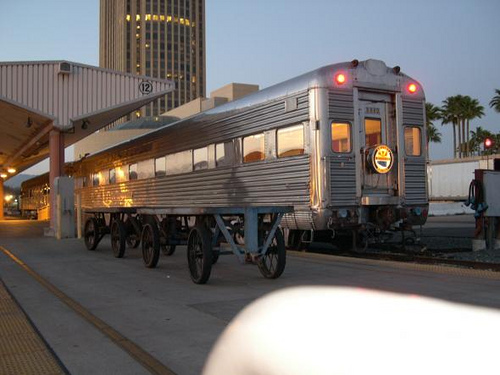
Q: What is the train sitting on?
A: Rails.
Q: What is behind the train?
A: Building.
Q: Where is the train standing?
A: At the station.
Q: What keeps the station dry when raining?
A: Roof covering.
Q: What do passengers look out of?
A: Windows.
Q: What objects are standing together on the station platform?
A: Wheels.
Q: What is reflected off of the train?
A: Sunset.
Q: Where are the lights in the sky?
A: In the building.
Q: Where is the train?
A: On the tracks.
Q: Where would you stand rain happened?
A: Under the overhang.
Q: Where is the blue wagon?
A: On the train platform.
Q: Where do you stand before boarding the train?
A: On the train platform.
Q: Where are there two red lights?
A: On the front of the train.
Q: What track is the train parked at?
A: Track 12.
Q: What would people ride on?
A: The train.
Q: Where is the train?
A: Parked at the platform.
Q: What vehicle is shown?
A: Train.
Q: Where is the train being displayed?
A: Station.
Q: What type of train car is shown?
A: Passenger.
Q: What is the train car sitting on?
A: Wheels.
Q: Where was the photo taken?
A: Station.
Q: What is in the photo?
A: A train.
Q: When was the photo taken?
A: Daytime.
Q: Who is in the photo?
A: Nobody.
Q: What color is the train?
A: Silver.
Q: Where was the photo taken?
A: At a train station.